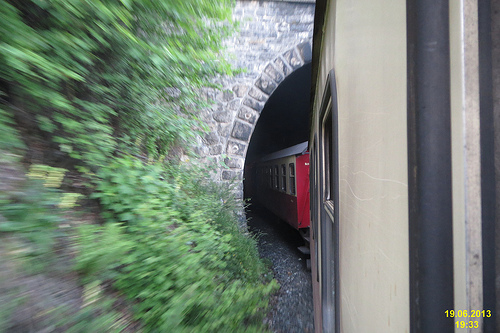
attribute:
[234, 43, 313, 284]
tunnel — very dark